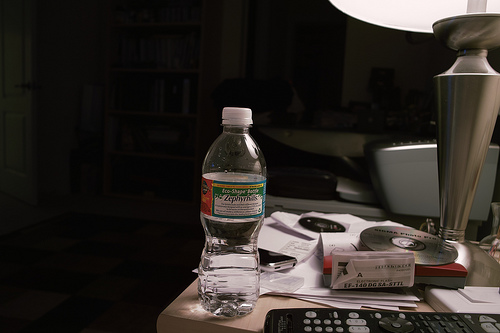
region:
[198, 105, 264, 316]
plastic bottle of water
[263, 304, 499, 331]
black electronic remote with white buttons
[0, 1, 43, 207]
white door is open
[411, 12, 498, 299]
silver lamp base on table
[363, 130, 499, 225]
printer is gray behind lamp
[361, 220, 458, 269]
compact disc by lamp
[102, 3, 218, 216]
wooden shelves against wall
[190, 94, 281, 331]
This is a bottle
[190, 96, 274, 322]
This is a bottle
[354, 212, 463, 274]
This is a CD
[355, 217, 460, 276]
This is a DvD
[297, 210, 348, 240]
This is a dvd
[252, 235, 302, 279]
This is a mobile phone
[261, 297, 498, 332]
This is a remote control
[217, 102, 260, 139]
Cap of a bottle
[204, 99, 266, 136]
White cap of a bottle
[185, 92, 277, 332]
some liquid in a bottle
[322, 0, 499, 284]
silver metal lamp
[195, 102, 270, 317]
plastic bottle with white cap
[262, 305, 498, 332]
black remote with white buttons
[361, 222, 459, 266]
silver CD with black writing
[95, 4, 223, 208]
tall light brown wood book case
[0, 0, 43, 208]
open white wood door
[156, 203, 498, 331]
messy white desk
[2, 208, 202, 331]
checkered area rug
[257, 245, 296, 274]
silver and black cellphone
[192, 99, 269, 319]
A half-empty water bottle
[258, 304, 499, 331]
A black remote control on a table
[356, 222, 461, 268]
A cd sitting on a paper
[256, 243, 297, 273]
A black and silver cell phone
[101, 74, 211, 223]
A book shelf against a wall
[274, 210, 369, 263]
A pile of papers on a table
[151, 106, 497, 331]
A table with a bottle, papers, cd's and a remote control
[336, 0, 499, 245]
A silver lamp with a white shade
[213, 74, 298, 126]
A CD player on a shelf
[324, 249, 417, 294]
A book of checks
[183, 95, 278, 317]
water bottle on the table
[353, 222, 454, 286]
the disk is silver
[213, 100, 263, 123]
lid on water bottle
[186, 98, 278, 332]
tall clear water bottle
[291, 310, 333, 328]
white buttons on remote